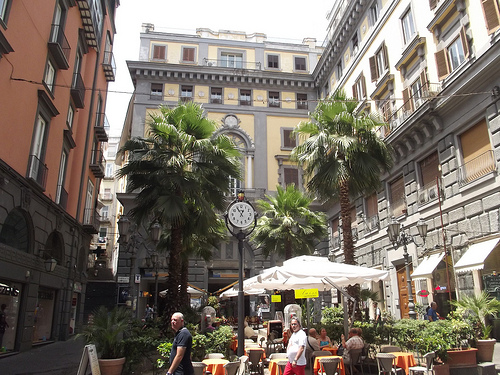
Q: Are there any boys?
A: No, there are no boys.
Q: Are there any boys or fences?
A: No, there are no boys or fences.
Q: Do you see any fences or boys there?
A: No, there are no boys or fences.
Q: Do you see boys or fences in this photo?
A: No, there are no boys or fences.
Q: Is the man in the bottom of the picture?
A: Yes, the man is in the bottom of the image.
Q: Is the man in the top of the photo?
A: No, the man is in the bottom of the image.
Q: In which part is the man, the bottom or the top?
A: The man is in the bottom of the image.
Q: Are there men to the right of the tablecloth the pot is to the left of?
A: Yes, there is a man to the right of the tablecloth.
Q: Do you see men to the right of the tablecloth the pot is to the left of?
A: Yes, there is a man to the right of the tablecloth.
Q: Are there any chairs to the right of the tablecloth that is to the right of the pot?
A: No, there is a man to the right of the tablecloth.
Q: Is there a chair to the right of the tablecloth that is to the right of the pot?
A: No, there is a man to the right of the tablecloth.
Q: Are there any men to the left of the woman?
A: Yes, there is a man to the left of the woman.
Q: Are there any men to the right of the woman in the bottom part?
A: No, the man is to the left of the woman.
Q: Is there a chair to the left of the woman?
A: No, there is a man to the left of the woman.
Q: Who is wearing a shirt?
A: The man is wearing a shirt.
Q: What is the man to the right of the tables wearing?
A: The man is wearing a shirt.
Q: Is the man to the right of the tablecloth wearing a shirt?
A: Yes, the man is wearing a shirt.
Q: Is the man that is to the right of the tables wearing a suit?
A: No, the man is wearing a shirt.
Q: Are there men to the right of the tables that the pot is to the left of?
A: Yes, there is a man to the right of the tables.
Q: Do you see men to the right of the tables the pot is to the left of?
A: Yes, there is a man to the right of the tables.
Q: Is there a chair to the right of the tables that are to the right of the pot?
A: No, there is a man to the right of the tables.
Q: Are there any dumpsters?
A: No, there are no dumpsters.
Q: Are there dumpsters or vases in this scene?
A: No, there are no dumpsters or vases.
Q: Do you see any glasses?
A: No, there are no glasses.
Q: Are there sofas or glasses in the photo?
A: No, there are no glasses or sofas.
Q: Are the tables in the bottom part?
A: Yes, the tables are in the bottom of the image.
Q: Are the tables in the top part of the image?
A: No, the tables are in the bottom of the image.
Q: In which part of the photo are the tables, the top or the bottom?
A: The tables are in the bottom of the image.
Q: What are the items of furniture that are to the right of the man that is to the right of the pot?
A: The pieces of furniture are tables.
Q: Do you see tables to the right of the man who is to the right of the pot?
A: Yes, there are tables to the right of the man.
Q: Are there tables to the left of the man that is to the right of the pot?
A: No, the tables are to the right of the man.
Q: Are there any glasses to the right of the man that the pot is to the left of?
A: No, there are tables to the right of the man.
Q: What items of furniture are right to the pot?
A: The pieces of furniture are tables.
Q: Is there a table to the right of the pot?
A: Yes, there are tables to the right of the pot.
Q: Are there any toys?
A: No, there are no toys.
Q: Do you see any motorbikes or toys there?
A: No, there are no toys or motorbikes.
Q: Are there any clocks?
A: Yes, there is a clock.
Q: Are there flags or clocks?
A: Yes, there is a clock.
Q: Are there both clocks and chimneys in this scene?
A: No, there is a clock but no chimneys.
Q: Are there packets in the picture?
A: No, there are no packets.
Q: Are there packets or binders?
A: No, there are no packets or binders.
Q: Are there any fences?
A: No, there are no fences.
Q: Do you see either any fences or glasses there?
A: No, there are no fences or glasses.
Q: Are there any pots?
A: Yes, there is a pot.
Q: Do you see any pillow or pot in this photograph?
A: Yes, there is a pot.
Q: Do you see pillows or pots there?
A: Yes, there is a pot.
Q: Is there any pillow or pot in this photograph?
A: Yes, there is a pot.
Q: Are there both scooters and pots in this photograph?
A: No, there is a pot but no scooters.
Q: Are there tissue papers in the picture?
A: No, there are no tissue papers.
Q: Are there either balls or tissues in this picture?
A: No, there are no tissues or balls.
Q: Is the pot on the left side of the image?
A: Yes, the pot is on the left of the image.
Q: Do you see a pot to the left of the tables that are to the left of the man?
A: Yes, there is a pot to the left of the tables.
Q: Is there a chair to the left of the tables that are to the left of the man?
A: No, there is a pot to the left of the tables.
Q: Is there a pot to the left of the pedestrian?
A: Yes, there is a pot to the left of the pedestrian.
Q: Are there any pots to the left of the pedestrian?
A: Yes, there is a pot to the left of the pedestrian.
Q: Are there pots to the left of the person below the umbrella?
A: Yes, there is a pot to the left of the pedestrian.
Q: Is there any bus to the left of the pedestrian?
A: No, there is a pot to the left of the pedestrian.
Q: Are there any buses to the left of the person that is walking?
A: No, there is a pot to the left of the pedestrian.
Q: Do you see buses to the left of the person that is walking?
A: No, there is a pot to the left of the pedestrian.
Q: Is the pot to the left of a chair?
A: No, the pot is to the left of a pedestrian.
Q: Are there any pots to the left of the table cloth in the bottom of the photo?
A: Yes, there is a pot to the left of the tablecloth.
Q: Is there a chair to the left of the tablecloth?
A: No, there is a pot to the left of the tablecloth.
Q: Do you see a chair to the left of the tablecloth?
A: No, there is a pot to the left of the tablecloth.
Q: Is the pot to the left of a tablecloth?
A: Yes, the pot is to the left of a tablecloth.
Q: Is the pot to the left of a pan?
A: No, the pot is to the left of a tablecloth.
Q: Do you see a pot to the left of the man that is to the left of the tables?
A: Yes, there is a pot to the left of the man.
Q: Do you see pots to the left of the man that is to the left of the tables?
A: Yes, there is a pot to the left of the man.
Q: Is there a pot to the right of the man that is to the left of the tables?
A: No, the pot is to the left of the man.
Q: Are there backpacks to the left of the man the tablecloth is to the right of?
A: No, there is a pot to the left of the man.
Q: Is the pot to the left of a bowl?
A: No, the pot is to the left of the man.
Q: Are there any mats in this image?
A: No, there are no mats.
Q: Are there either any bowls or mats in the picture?
A: No, there are no mats or bowls.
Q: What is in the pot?
A: The plant is in the pot.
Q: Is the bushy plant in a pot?
A: Yes, the plant is in a pot.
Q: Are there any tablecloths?
A: Yes, there is a tablecloth.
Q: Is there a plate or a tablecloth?
A: Yes, there is a tablecloth.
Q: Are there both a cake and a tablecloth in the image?
A: No, there is a tablecloth but no cakes.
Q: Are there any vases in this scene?
A: No, there are no vases.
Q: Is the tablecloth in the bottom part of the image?
A: Yes, the tablecloth is in the bottom of the image.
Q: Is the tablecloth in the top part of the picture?
A: No, the tablecloth is in the bottom of the image.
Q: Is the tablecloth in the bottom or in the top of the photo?
A: The tablecloth is in the bottom of the image.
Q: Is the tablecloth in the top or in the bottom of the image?
A: The tablecloth is in the bottom of the image.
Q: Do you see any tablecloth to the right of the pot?
A: Yes, there is a tablecloth to the right of the pot.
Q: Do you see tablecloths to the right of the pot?
A: Yes, there is a tablecloth to the right of the pot.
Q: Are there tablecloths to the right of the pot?
A: Yes, there is a tablecloth to the right of the pot.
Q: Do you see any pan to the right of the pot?
A: No, there is a tablecloth to the right of the pot.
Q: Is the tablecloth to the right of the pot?
A: Yes, the tablecloth is to the right of the pot.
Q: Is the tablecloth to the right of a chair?
A: No, the tablecloth is to the right of the pot.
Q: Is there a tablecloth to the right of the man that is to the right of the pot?
A: Yes, there is a tablecloth to the right of the man.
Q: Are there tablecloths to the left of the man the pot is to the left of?
A: No, the tablecloth is to the right of the man.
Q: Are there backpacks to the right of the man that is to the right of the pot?
A: No, there is a tablecloth to the right of the man.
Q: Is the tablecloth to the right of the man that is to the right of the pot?
A: Yes, the tablecloth is to the right of the man.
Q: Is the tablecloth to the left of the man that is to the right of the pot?
A: No, the tablecloth is to the right of the man.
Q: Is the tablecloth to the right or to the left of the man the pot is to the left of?
A: The tablecloth is to the right of the man.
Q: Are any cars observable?
A: No, there are no cars.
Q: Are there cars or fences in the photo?
A: No, there are no cars or fences.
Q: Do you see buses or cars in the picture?
A: No, there are no buses or cars.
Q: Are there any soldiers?
A: No, there are no soldiers.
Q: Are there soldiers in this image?
A: No, there are no soldiers.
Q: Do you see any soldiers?
A: No, there are no soldiers.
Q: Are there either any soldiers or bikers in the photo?
A: No, there are no soldiers or bikers.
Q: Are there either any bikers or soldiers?
A: No, there are no soldiers or bikers.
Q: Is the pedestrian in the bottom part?
A: Yes, the pedestrian is in the bottom of the image.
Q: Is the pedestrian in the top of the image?
A: No, the pedestrian is in the bottom of the image.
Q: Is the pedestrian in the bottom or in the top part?
A: The pedestrian is in the bottom of the image.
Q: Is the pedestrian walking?
A: Yes, the pedestrian is walking.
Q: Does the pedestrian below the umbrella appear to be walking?
A: Yes, the pedestrian is walking.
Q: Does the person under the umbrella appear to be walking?
A: Yes, the pedestrian is walking.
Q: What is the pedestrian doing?
A: The pedestrian is walking.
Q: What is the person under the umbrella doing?
A: The pedestrian is walking.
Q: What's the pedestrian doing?
A: The pedestrian is walking.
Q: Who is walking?
A: The pedestrian is walking.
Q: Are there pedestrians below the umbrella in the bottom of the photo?
A: Yes, there is a pedestrian below the umbrella.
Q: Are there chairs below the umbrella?
A: No, there is a pedestrian below the umbrella.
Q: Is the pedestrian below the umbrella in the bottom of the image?
A: Yes, the pedestrian is below the umbrella.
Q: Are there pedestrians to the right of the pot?
A: Yes, there is a pedestrian to the right of the pot.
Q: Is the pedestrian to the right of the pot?
A: Yes, the pedestrian is to the right of the pot.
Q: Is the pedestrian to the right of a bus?
A: No, the pedestrian is to the right of the pot.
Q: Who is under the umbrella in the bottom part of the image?
A: The pedestrian is under the umbrella.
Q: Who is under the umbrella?
A: The pedestrian is under the umbrella.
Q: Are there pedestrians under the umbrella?
A: Yes, there is a pedestrian under the umbrella.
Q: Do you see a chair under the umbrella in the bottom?
A: No, there is a pedestrian under the umbrella.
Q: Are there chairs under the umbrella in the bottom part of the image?
A: No, there is a pedestrian under the umbrella.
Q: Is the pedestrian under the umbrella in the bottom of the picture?
A: Yes, the pedestrian is under the umbrella.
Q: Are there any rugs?
A: No, there are no rugs.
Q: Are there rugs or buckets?
A: No, there are no rugs or buckets.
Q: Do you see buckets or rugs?
A: No, there are no rugs or buckets.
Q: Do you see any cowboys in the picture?
A: No, there are no cowboys.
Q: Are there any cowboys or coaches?
A: No, there are no cowboys or coaches.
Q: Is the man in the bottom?
A: Yes, the man is in the bottom of the image.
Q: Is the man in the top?
A: No, the man is in the bottom of the image.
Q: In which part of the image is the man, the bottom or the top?
A: The man is in the bottom of the image.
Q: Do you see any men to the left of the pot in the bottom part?
A: No, the man is to the right of the pot.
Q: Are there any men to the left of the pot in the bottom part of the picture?
A: No, the man is to the right of the pot.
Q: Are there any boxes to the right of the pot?
A: No, there is a man to the right of the pot.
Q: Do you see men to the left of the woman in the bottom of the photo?
A: Yes, there is a man to the left of the woman.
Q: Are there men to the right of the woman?
A: No, the man is to the left of the woman.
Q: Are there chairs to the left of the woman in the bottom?
A: No, there is a man to the left of the woman.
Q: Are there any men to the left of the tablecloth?
A: Yes, there is a man to the left of the tablecloth.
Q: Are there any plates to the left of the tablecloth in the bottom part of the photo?
A: No, there is a man to the left of the tablecloth.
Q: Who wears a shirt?
A: The man wears a shirt.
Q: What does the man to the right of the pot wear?
A: The man wears a shirt.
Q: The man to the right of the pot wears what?
A: The man wears a shirt.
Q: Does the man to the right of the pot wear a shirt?
A: Yes, the man wears a shirt.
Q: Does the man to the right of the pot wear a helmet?
A: No, the man wears a shirt.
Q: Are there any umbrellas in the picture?
A: Yes, there is an umbrella.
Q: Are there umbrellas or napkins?
A: Yes, there is an umbrella.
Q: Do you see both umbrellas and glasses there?
A: No, there is an umbrella but no glasses.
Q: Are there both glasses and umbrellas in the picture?
A: No, there is an umbrella but no glasses.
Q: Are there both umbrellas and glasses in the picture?
A: No, there is an umbrella but no glasses.